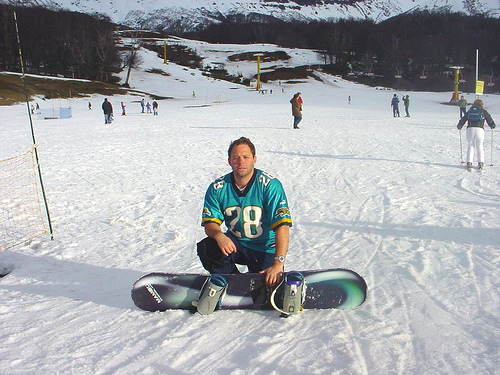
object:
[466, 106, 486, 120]
backpack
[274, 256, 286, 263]
watch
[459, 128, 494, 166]
ski poles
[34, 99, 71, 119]
hole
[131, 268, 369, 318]
snowboard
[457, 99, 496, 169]
lady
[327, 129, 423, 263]
trees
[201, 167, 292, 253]
jersey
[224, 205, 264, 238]
28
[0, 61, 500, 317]
ground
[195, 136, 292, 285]
man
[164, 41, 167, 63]
lift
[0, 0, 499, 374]
snow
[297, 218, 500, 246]
shadow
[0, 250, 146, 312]
shadow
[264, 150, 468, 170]
shadow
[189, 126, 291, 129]
shadow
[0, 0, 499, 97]
hills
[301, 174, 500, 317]
tracks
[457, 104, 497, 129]
coat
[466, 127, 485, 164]
pants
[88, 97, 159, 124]
people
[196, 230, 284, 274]
pants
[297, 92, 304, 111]
child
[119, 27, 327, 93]
slope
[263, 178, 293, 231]
sleeve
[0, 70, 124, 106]
grass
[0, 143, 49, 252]
net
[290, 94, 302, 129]
person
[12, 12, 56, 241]
fencing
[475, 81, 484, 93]
information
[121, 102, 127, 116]
child